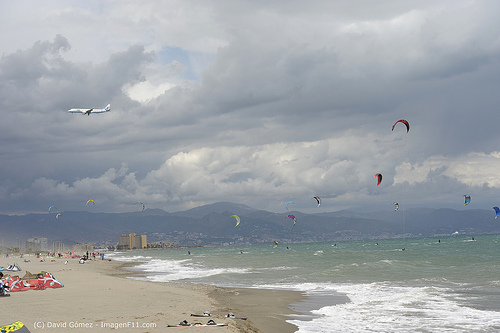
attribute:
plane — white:
[66, 98, 109, 123]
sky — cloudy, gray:
[166, 70, 233, 111]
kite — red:
[383, 112, 424, 138]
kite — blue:
[447, 186, 474, 211]